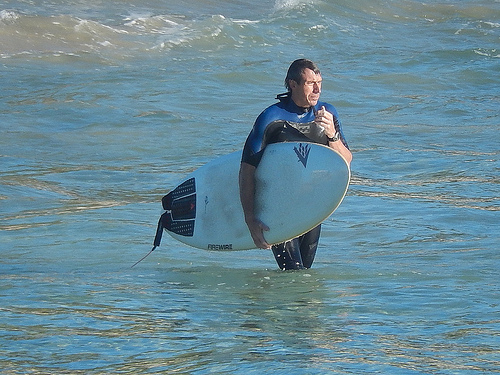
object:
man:
[237, 58, 354, 270]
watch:
[326, 131, 341, 141]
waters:
[1, 0, 498, 372]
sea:
[0, 0, 499, 374]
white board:
[154, 142, 349, 253]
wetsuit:
[239, 100, 351, 271]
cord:
[127, 217, 164, 271]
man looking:
[282, 58, 324, 108]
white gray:
[0, 0, 337, 60]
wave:
[0, 0, 500, 61]